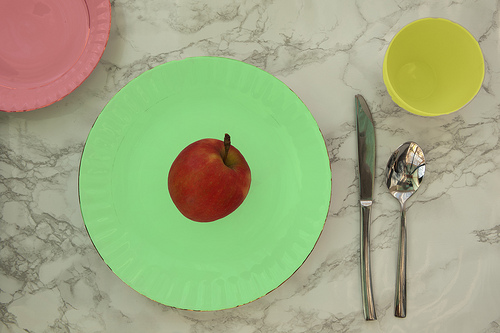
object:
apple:
[167, 133, 251, 222]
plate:
[77, 56, 333, 312]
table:
[0, 0, 499, 333]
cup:
[383, 18, 485, 117]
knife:
[354, 93, 376, 320]